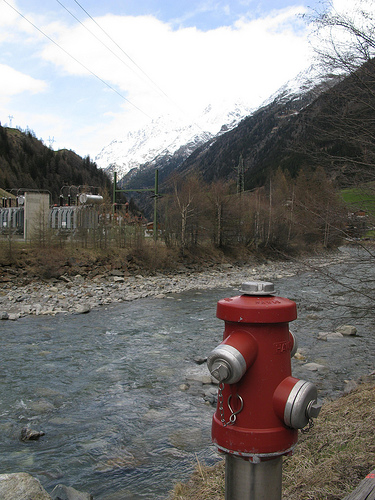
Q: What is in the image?
A: Hydrant.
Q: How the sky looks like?
A: Cloud.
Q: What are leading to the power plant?
A: Lines.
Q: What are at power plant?
A: Transformers.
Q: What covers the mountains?
A: Snow.`.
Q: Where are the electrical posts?
A: By hill.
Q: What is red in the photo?
A: Hydrant.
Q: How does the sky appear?
A: Cloudy.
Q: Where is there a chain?
A: On fire hydrant.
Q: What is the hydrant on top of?
A: Pole.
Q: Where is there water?
A: In creek.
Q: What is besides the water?
A: Fence.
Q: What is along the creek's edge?
A: Rocks.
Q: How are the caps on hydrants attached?
A: Bolts.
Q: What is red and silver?
A: Fire hydrant.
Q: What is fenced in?
A: Power area.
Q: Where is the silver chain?
A: On fire hydrant.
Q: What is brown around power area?
A: Dead weeds.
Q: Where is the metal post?
A: Under hydrant.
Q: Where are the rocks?
A: Along the sides.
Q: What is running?
A: Stream of water.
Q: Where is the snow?
A: On the mountain.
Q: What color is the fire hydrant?
A: Red.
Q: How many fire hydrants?
A: 1.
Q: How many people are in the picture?
A: None.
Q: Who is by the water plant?
A: No one.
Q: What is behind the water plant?
A: Mountain.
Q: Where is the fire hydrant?
A: In front of river.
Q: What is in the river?
A: Rocks.